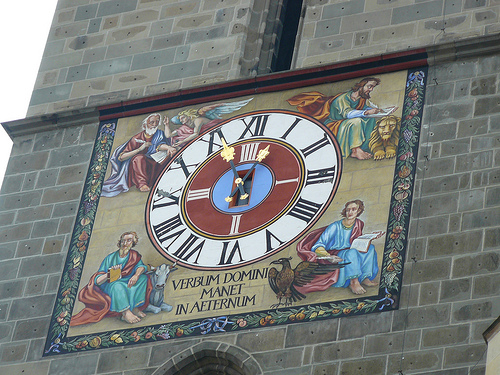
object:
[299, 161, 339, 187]
numerals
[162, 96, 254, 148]
angel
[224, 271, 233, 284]
words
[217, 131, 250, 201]
hand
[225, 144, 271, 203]
hand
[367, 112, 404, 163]
lion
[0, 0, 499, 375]
building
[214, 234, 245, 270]
numeral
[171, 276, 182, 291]
word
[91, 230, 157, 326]
man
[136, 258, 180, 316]
cow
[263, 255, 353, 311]
bird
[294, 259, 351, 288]
wings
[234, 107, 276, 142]
numberal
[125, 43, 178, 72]
bricks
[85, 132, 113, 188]
design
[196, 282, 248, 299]
manet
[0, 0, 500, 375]
wall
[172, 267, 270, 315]
phrase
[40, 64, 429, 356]
figure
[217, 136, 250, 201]
minute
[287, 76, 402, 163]
pictures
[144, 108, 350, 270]
clock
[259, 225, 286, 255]
roman numerals